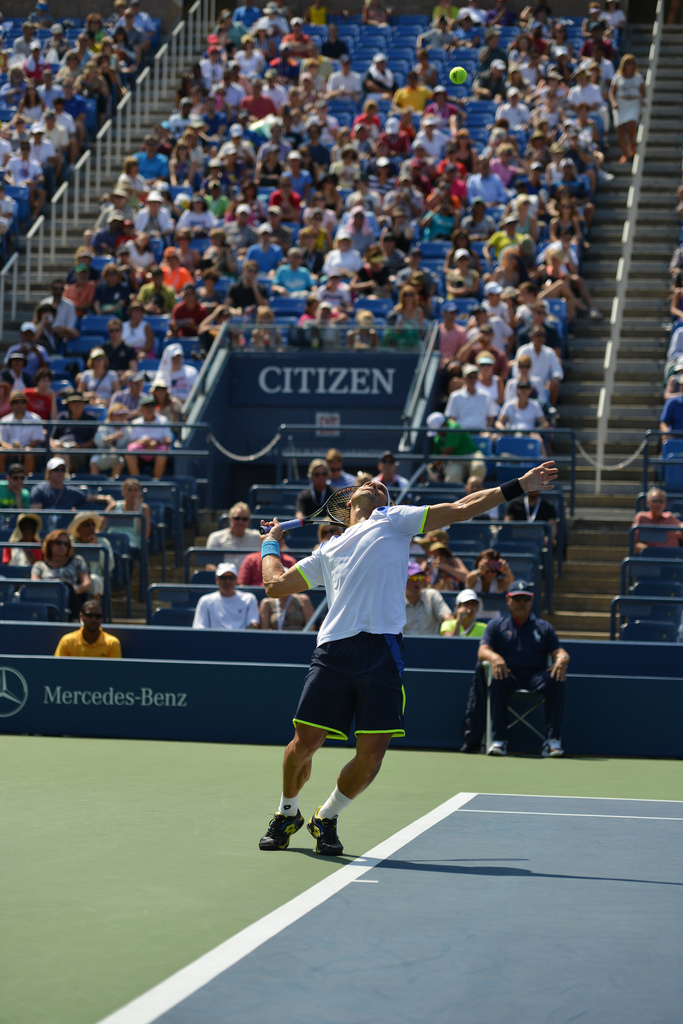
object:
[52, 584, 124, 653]
person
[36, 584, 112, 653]
shirt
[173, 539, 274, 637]
person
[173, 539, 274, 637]
shirt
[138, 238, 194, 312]
shirt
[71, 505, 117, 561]
person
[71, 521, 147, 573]
shirt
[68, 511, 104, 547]
hat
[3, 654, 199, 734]
advertisement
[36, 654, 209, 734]
wall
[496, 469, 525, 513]
band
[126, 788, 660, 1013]
line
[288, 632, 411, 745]
pants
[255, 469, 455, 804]
man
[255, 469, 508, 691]
shirt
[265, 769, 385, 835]
socks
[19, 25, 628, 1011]
sunny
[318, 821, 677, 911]
shadow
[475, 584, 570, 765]
man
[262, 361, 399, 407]
writing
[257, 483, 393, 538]
racquet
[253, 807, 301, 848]
shoes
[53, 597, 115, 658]
shirt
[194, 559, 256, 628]
shirt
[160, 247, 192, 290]
shirt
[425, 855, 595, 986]
surface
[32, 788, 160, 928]
surface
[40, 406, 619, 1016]
court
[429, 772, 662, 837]
line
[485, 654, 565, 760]
chair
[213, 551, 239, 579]
hat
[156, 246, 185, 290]
person